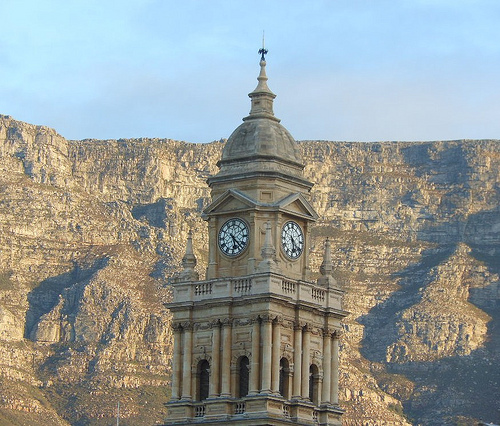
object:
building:
[162, 30, 348, 424]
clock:
[219, 219, 248, 257]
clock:
[281, 220, 303, 259]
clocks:
[218, 218, 304, 262]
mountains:
[0, 112, 499, 425]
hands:
[228, 231, 244, 250]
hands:
[289, 235, 299, 256]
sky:
[0, 0, 497, 144]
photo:
[0, 1, 498, 425]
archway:
[195, 356, 210, 415]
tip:
[259, 28, 267, 55]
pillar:
[260, 313, 273, 397]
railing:
[191, 399, 207, 420]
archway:
[233, 354, 249, 416]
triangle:
[201, 189, 258, 217]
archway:
[278, 354, 291, 416]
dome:
[216, 64, 304, 174]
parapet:
[165, 271, 343, 304]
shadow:
[360, 213, 497, 425]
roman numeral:
[230, 219, 238, 227]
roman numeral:
[235, 221, 240, 227]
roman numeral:
[239, 225, 245, 233]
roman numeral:
[240, 232, 248, 238]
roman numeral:
[239, 240, 247, 246]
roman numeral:
[235, 244, 241, 252]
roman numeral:
[229, 248, 235, 256]